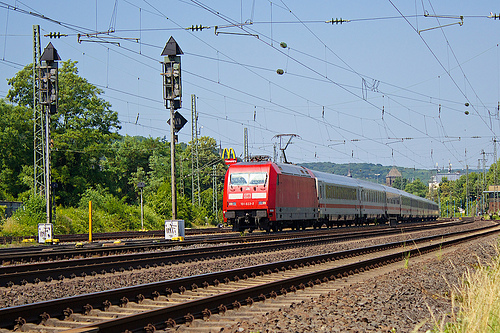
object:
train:
[224, 161, 442, 231]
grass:
[460, 281, 489, 328]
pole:
[160, 31, 189, 239]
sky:
[340, 31, 408, 61]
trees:
[77, 136, 147, 190]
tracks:
[238, 244, 392, 284]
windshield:
[229, 172, 267, 186]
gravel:
[354, 287, 420, 320]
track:
[238, 250, 347, 294]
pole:
[82, 198, 107, 250]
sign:
[218, 147, 244, 165]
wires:
[246, 78, 414, 165]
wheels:
[259, 222, 335, 232]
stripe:
[322, 201, 410, 216]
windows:
[324, 184, 362, 201]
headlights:
[224, 198, 271, 209]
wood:
[244, 303, 281, 315]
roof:
[428, 171, 464, 186]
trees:
[444, 184, 468, 206]